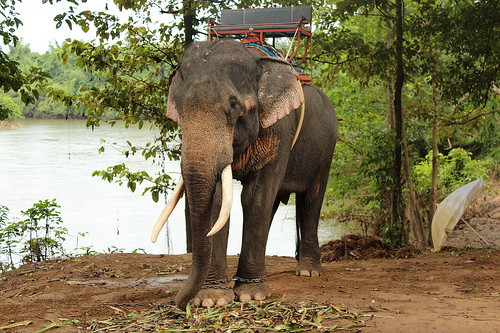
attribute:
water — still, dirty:
[0, 117, 374, 274]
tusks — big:
[146, 162, 235, 246]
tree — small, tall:
[372, 17, 465, 237]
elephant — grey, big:
[128, 0, 356, 330]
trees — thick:
[28, 48, 173, 124]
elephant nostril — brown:
[130, 113, 272, 239]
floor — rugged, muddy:
[0, 252, 498, 332]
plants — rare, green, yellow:
[306, 6, 496, 247]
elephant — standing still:
[162, 24, 332, 308]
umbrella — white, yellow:
[428, 177, 497, 255]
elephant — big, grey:
[152, 32, 344, 309]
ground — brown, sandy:
[374, 260, 474, 330]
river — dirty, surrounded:
[4, 116, 185, 254]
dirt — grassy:
[347, 234, 375, 253]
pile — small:
[101, 300, 332, 331]